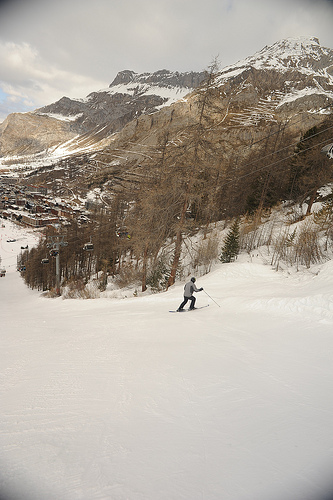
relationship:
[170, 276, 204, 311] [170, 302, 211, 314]
skier has two skis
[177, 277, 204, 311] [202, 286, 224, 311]
skier has two ski poles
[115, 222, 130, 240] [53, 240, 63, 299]
ski lift on a tower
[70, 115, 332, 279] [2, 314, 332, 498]
trees along slope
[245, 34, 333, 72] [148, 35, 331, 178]
snow covered peaks on mountain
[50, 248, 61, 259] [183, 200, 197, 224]
skiers on lift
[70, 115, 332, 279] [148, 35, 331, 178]
evergreens on mountain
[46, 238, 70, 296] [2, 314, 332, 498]
ski lift tower on slope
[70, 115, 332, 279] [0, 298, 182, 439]
pine trees along ski trail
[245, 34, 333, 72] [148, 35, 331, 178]
snow on mountain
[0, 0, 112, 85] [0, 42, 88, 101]
sky has clouds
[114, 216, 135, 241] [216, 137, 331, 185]
ski chairs secured by cables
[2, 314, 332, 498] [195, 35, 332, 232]
white snow in mountains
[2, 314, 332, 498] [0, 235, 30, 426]
white snow on trails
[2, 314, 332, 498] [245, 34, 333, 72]
white snow on peaks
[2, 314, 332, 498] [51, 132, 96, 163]
white snow along ski trails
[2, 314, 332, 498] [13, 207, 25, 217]
white snow on roofs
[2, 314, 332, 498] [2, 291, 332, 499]
white snow on slope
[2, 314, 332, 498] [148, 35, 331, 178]
white snow in mountain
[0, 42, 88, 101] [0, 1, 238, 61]
clouds in gray sky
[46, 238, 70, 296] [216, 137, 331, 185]
chair lift has cables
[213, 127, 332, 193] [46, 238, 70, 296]
thin cables between towers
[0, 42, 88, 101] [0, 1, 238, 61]
snow clouds in sky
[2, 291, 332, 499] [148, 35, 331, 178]
slope on mountain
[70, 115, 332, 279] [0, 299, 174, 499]
pine trees bordering trail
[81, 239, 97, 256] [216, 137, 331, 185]
lift chairs on tower cables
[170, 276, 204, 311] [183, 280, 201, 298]
skiers has a grey jacket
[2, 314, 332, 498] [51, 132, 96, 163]
snow covered ski trails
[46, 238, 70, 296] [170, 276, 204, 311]
ski lift transports skiers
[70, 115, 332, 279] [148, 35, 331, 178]
forest in mountain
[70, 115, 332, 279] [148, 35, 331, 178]
pine trees in mountain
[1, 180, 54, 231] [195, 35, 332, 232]
city in mountains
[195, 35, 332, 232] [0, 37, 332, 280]
mountains in valley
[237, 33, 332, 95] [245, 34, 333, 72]
peaks have snow